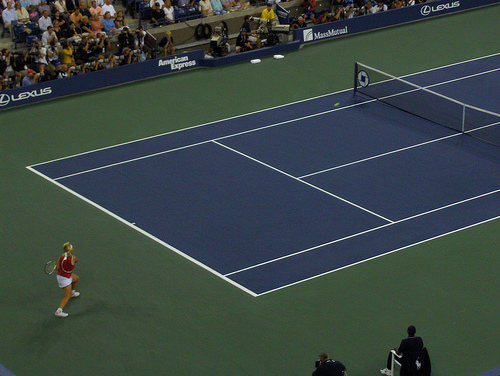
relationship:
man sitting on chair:
[394, 325, 424, 374] [383, 350, 420, 372]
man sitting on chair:
[380, 325, 424, 375] [386, 348, 419, 371]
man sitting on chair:
[380, 325, 424, 375] [381, 343, 436, 373]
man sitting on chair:
[380, 325, 424, 375] [379, 350, 425, 372]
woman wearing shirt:
[47, 237, 87, 324] [54, 251, 78, 275]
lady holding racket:
[54, 241, 79, 317] [43, 258, 59, 277]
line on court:
[212, 134, 395, 232] [23, 51, 484, 298]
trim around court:
[4, 1, 484, 373] [23, 51, 484, 298]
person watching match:
[0, 0, 419, 88] [11, 75, 461, 328]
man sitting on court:
[380, 325, 424, 375] [13, 10, 479, 373]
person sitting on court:
[301, 346, 349, 374] [13, 10, 479, 373]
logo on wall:
[416, 0, 468, 13] [298, 6, 483, 38]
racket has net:
[40, 260, 60, 276] [46, 264, 54, 273]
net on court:
[348, 61, 484, 150] [23, 51, 484, 298]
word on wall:
[1, 88, 62, 104] [1, 56, 147, 119]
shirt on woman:
[56, 255, 75, 279] [45, 234, 84, 323]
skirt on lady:
[54, 272, 76, 291] [54, 241, 79, 317]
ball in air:
[331, 99, 341, 109] [231, 70, 403, 145]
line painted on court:
[150, 104, 353, 279] [23, 51, 484, 298]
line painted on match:
[150, 104, 353, 279] [25, 57, 500, 301]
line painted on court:
[150, 104, 353, 279] [33, 68, 488, 308]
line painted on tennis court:
[150, 104, 353, 279] [42, 54, 490, 329]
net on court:
[355, 61, 499, 147] [47, 36, 497, 321]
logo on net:
[356, 71, 373, 86] [348, 60, 492, 155]